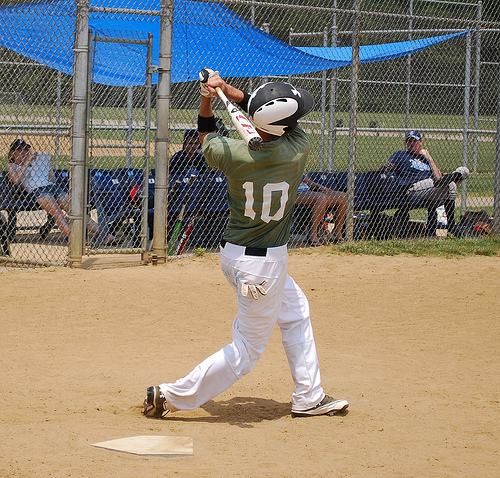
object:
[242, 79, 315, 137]
helmet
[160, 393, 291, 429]
shadow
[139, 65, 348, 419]
player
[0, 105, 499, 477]
ground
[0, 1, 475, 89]
cloth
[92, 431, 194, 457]
home plate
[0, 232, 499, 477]
baseball field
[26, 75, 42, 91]
leaves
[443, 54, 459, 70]
leaves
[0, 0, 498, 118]
tree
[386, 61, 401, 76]
leaves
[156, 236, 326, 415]
pants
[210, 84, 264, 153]
bat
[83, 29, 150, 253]
door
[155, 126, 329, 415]
uniform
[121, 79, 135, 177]
chain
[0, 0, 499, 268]
fence